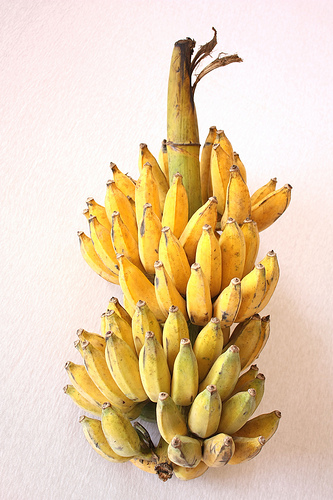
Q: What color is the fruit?
A: Yellow.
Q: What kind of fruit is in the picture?
A: A banana.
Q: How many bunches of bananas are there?
A: One.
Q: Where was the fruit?
A: Laying on the ground.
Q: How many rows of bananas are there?
A: Six.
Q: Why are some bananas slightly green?
A: They aren't ripe.